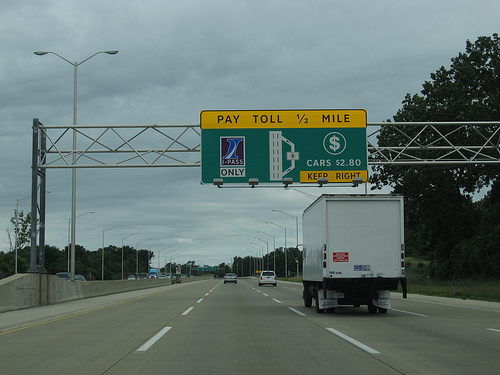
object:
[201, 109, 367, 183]
sign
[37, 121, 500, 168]
pole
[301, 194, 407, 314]
truck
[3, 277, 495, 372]
pavement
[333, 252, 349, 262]
sign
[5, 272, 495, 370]
road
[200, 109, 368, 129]
yellow bar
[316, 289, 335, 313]
wheel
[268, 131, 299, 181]
white image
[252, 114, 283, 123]
writing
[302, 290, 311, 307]
wheel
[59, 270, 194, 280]
side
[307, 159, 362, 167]
writing